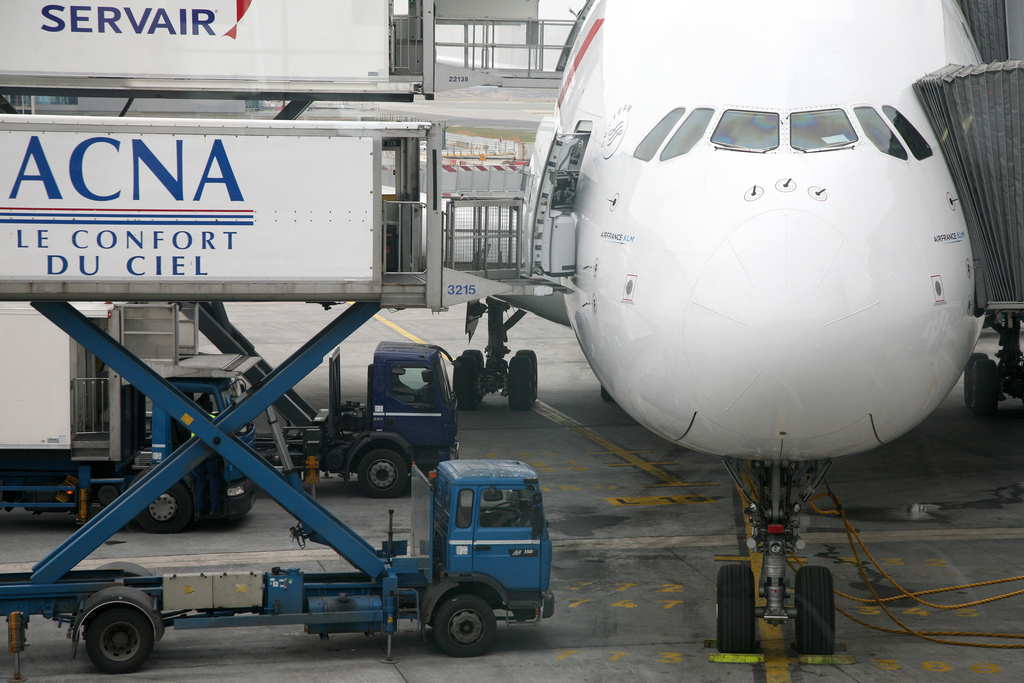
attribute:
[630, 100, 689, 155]
window — glass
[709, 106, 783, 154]
window — glass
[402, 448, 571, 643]
vehicle — blue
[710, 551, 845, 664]
wheels — black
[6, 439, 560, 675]
truck — blue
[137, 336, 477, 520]
truck — blue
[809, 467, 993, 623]
cord — yellow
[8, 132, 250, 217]
letters — blue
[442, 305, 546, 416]
wheels — big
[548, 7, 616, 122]
stripe — red, blue, white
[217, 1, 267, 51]
part — red